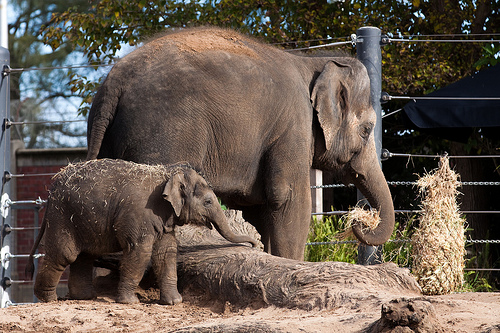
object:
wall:
[263, 100, 498, 149]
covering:
[399, 67, 498, 143]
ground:
[3, 292, 500, 331]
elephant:
[88, 25, 396, 263]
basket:
[410, 150, 466, 294]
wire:
[383, 95, 498, 101]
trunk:
[352, 154, 394, 245]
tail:
[83, 90, 122, 165]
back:
[51, 157, 145, 183]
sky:
[7, 7, 19, 23]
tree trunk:
[407, 166, 467, 295]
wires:
[381, 32, 498, 46]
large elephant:
[85, 26, 396, 247]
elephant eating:
[305, 53, 394, 248]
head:
[161, 168, 264, 250]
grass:
[379, 207, 444, 278]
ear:
[309, 59, 355, 151]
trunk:
[212, 214, 261, 250]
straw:
[415, 157, 468, 297]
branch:
[3, 0, 136, 69]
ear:
[162, 172, 187, 217]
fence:
[2, 21, 499, 299]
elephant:
[25, 156, 263, 306]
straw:
[49, 158, 163, 190]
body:
[57, 158, 163, 253]